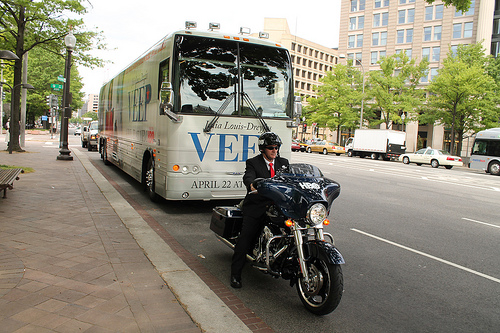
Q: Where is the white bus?
A: Behind the motorcycle.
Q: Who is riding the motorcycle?
A: The man.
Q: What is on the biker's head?
A: A helmet.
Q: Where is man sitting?
A: On motorcycle.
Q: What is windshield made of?
A: Glass.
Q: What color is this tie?
A: Red in color.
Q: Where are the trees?
A: Next to street.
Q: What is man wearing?
A: A suit.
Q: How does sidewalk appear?
A: Paved.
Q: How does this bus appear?
A: Blue and white in color.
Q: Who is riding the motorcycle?
A: A man.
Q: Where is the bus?
A: On the street.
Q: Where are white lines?
A: On the pavement.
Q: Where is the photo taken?
A: In a city.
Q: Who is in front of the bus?
A: A man.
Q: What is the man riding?
A: A motorcycle.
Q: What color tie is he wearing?
A: Red.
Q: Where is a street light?
A: Next to the bus.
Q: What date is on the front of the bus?
A: April 22.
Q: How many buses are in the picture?
A: Two.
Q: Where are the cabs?
A: Going the other direction.